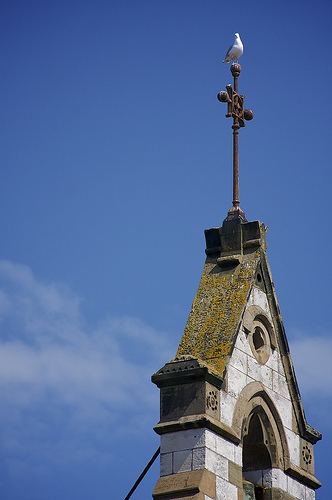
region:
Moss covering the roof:
[186, 257, 247, 377]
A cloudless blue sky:
[14, 95, 166, 214]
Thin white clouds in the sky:
[7, 314, 146, 443]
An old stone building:
[162, 67, 301, 498]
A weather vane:
[205, 64, 272, 225]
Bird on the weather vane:
[203, 26, 256, 81]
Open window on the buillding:
[238, 311, 274, 365]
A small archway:
[223, 396, 289, 497]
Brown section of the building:
[154, 358, 229, 430]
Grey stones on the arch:
[160, 434, 231, 475]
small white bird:
[219, 28, 255, 68]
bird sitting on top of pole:
[215, 21, 250, 66]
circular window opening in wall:
[243, 298, 280, 363]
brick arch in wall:
[234, 376, 292, 498]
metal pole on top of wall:
[213, 59, 261, 221]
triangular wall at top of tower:
[137, 51, 321, 497]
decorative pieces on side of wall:
[143, 349, 231, 420]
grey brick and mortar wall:
[148, 214, 331, 496]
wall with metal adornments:
[145, 200, 330, 495]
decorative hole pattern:
[205, 386, 224, 416]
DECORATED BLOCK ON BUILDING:
[206, 383, 219, 416]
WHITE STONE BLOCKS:
[160, 435, 219, 470]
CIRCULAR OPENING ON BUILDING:
[243, 306, 279, 364]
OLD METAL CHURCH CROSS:
[217, 62, 255, 222]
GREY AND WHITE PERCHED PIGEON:
[224, 30, 252, 66]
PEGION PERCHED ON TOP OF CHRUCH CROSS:
[211, 24, 256, 217]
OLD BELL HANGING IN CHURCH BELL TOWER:
[235, 469, 258, 498]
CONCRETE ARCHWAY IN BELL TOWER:
[235, 379, 296, 472]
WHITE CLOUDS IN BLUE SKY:
[40, 328, 152, 396]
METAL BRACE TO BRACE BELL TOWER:
[106, 438, 167, 499]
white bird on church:
[222, 33, 251, 61]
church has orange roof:
[186, 231, 233, 381]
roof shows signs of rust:
[170, 207, 255, 430]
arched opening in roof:
[216, 368, 297, 496]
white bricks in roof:
[155, 417, 261, 458]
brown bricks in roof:
[150, 446, 324, 489]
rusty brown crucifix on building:
[201, 65, 252, 197]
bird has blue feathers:
[211, 41, 249, 73]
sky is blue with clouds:
[7, 265, 108, 462]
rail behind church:
[120, 443, 169, 498]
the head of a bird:
[230, 27, 242, 41]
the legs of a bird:
[229, 55, 242, 65]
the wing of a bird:
[224, 43, 235, 58]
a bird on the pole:
[219, 30, 245, 69]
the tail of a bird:
[218, 55, 232, 66]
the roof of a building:
[147, 220, 259, 385]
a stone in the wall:
[169, 448, 196, 475]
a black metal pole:
[119, 442, 163, 499]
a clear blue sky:
[0, 0, 331, 499]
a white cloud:
[0, 255, 330, 453]